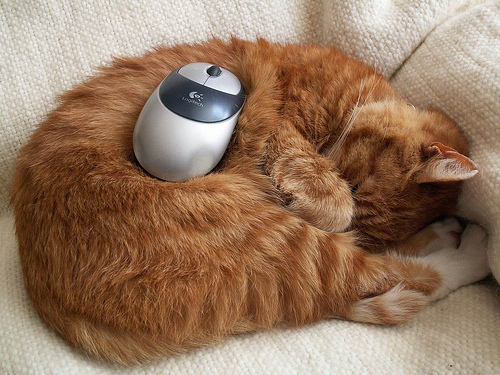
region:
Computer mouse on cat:
[131, 51, 246, 184]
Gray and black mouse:
[135, 60, 246, 181]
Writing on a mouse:
[181, 89, 208, 106]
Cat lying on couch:
[10, 39, 499, 361]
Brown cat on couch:
[14, 41, 492, 361]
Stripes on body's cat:
[131, 179, 406, 330]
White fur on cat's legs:
[407, 216, 496, 301]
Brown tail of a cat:
[76, 311, 338, 373]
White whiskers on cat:
[327, 70, 372, 164]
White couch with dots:
[0, 0, 499, 374]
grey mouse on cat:
[118, 46, 245, 211]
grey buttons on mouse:
[183, 51, 233, 116]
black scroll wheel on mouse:
[203, 56, 225, 101]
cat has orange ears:
[431, 103, 488, 181]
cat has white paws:
[393, 184, 499, 292]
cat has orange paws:
[274, 129, 346, 242]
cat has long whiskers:
[321, 81, 393, 201]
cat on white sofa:
[219, 338, 322, 373]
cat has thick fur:
[28, 56, 175, 322]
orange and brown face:
[338, 99, 454, 251]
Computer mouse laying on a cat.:
[140, 40, 252, 193]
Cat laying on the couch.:
[15, 8, 490, 343]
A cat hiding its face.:
[321, 104, 478, 251]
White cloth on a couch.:
[249, 336, 343, 373]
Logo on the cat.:
[182, 85, 207, 110]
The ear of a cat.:
[421, 134, 478, 202]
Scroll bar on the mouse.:
[207, 60, 222, 77]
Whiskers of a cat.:
[326, 83, 380, 166]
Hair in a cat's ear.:
[431, 155, 461, 176]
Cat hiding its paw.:
[281, 172, 358, 242]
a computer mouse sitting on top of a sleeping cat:
[12, 35, 491, 370]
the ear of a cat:
[401, 139, 481, 194]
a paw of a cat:
[275, 160, 360, 236]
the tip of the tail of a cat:
[359, 289, 436, 329]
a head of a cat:
[330, 95, 482, 240]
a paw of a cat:
[424, 207, 476, 254]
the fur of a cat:
[39, 195, 161, 290]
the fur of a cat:
[229, 225, 313, 296]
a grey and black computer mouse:
[125, 57, 252, 187]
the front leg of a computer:
[242, 84, 364, 239]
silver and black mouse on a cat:
[126, 46, 258, 201]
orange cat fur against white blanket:
[27, 256, 327, 369]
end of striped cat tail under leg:
[338, 275, 433, 338]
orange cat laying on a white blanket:
[5, 27, 496, 360]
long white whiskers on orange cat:
[331, 60, 381, 165]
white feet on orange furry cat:
[393, 218, 495, 303]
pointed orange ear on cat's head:
[411, 136, 483, 198]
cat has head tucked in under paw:
[294, 120, 405, 245]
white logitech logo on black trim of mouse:
[174, 80, 216, 125]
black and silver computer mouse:
[126, 59, 254, 199]